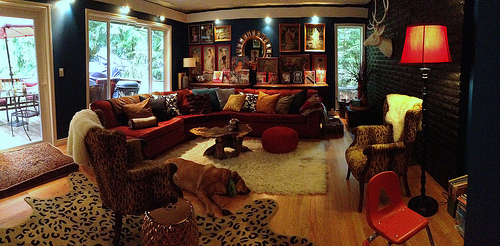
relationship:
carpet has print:
[27, 173, 135, 245] [71, 199, 83, 205]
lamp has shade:
[402, 24, 456, 218] [397, 26, 455, 66]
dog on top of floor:
[159, 152, 257, 218] [282, 197, 362, 241]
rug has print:
[9, 181, 315, 245] [71, 199, 83, 205]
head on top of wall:
[360, 0, 396, 61] [394, 7, 428, 22]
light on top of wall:
[157, 12, 167, 24] [58, 17, 77, 34]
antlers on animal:
[362, 0, 393, 30] [360, 0, 396, 61]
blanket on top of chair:
[66, 107, 110, 165] [66, 106, 182, 244]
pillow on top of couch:
[120, 99, 157, 119] [91, 86, 327, 152]